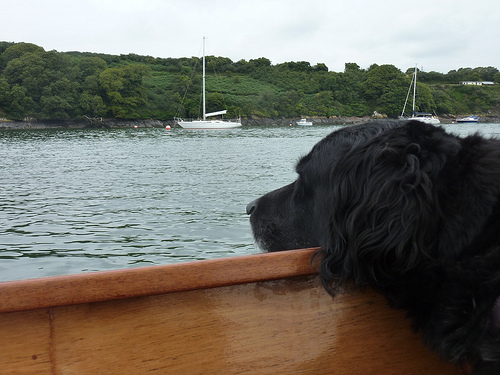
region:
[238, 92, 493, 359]
a black dog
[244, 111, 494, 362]
the dog is resting on a ledge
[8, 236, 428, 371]
the ledge is wooden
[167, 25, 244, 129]
a boat on the water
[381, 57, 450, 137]
a boat on the water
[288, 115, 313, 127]
a boat on the water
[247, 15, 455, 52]
the sky is cloudy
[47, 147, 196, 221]
the water is calm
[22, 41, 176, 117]
the trees with green leaves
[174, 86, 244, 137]
the boat is white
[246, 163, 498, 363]
dog resting on rail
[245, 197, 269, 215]
dog has black nose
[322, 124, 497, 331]
dog has black fur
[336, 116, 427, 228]
dog's ears lying flat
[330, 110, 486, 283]
dog has black ears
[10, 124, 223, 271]
water shows some ripples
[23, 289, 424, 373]
railing is brown wood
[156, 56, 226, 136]
white boat in distance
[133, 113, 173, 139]
buoys next to white boat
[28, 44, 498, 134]
forest of trees behind boats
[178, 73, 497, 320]
a dog on the boat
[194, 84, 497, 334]
a dog on the water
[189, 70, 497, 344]
a black dog with head on boat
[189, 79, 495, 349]
a black dog on boat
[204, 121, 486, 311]
a black dog on water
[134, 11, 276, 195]
boat in the water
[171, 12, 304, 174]
sailboat on the water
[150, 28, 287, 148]
sail boat in the water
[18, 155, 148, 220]
a body of water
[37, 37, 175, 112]
an area of trees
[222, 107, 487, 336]
dog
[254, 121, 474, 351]
black dog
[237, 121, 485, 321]
black dog with head overlooking river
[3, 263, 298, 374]
wooden railing of river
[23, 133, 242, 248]
calm green water of river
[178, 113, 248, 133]
white boat docked on river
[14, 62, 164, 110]
trees with green leaves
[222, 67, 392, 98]
trees with green leaves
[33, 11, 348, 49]
white clouds against blue sky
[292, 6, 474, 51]
white clouds against blue sky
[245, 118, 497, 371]
a black dog.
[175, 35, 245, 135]
a sail boat on water.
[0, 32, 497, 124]
a forest of trees.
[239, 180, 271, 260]
a nose on a dog.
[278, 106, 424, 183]
the top of a dogs head.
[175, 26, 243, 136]
a boat on choppy water.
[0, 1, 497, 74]
a cloudy gray sky.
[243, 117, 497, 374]
a black dog on a boat.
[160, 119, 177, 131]
an object in the water.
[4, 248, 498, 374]
a wooden section of a boat.